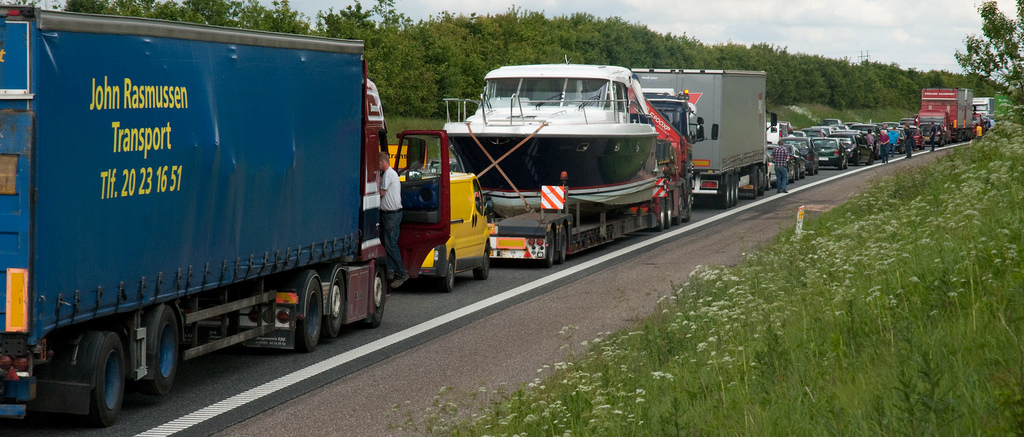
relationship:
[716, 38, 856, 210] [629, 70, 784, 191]
boat behind truck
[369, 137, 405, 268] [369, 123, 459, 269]
person standing in door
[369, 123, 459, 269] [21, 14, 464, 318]
door of truck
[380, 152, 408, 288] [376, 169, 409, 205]
person wearing shirt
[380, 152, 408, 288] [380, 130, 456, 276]
person at door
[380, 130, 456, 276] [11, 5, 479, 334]
door of truck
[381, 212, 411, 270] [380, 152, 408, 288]
pants of person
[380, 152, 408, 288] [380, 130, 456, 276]
person standing in door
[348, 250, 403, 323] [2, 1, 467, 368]
front tire of truck